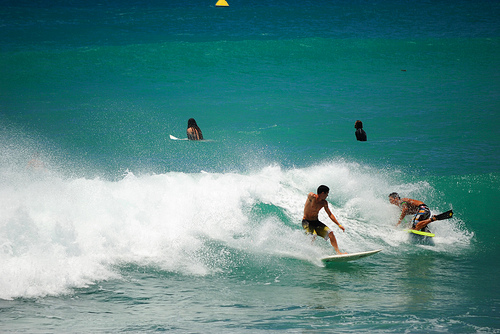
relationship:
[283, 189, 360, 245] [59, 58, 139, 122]
surfer in ocean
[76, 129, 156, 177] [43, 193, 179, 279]
white and green are wave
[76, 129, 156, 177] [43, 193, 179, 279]
white and green ocean wave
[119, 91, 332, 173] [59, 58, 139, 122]
photo of ocean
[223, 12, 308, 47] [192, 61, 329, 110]
blue portion of water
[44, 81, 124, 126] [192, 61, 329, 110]
green portion of water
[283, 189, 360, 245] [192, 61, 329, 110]
surfer in water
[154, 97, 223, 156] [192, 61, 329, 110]
person in water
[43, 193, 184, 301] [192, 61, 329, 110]
wave in water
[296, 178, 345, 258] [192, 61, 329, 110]
man in water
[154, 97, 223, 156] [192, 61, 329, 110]
woman in water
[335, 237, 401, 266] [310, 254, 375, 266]
top of surfboard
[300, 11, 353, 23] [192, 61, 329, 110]
dark line in water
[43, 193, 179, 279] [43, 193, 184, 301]
wave water wave